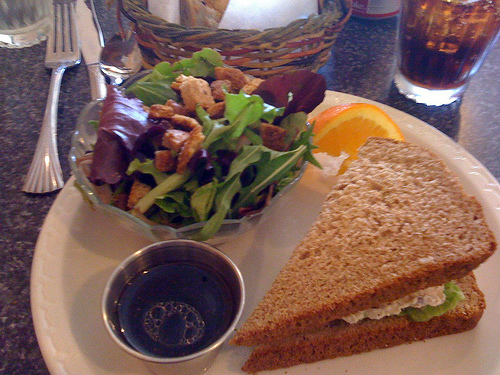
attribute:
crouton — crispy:
[179, 79, 213, 109]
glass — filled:
[369, 7, 499, 82]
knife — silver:
[71, 0, 111, 126]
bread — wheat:
[305, 157, 482, 332]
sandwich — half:
[201, 135, 481, 362]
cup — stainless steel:
[82, 231, 250, 365]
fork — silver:
[15, 1, 82, 195]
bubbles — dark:
[132, 292, 216, 347]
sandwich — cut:
[228, 135, 494, 373]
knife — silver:
[59, 7, 99, 197]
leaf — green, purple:
[253, 65, 327, 115]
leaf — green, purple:
[212, 88, 264, 142]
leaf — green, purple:
[102, 81, 163, 153]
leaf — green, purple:
[87, 130, 126, 189]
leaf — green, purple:
[233, 142, 313, 212]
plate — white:
[29, 86, 497, 373]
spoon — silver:
[98, 31, 143, 89]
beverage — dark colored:
[393, 4, 493, 84]